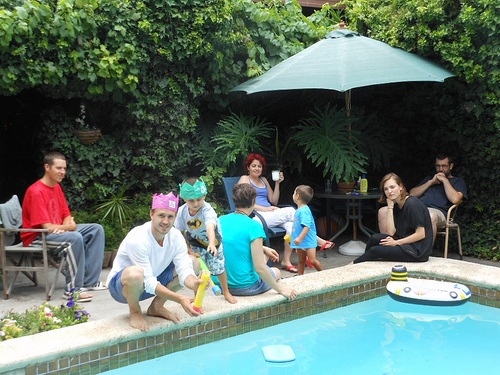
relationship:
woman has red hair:
[243, 153, 339, 274] [243, 148, 270, 170]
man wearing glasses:
[419, 150, 468, 237] [435, 161, 451, 168]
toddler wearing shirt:
[291, 181, 321, 286] [290, 205, 323, 254]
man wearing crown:
[100, 191, 203, 332] [149, 186, 180, 213]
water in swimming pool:
[380, 326, 471, 367] [7, 250, 499, 369]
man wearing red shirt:
[17, 148, 111, 305] [17, 174, 76, 251]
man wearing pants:
[17, 148, 111, 305] [27, 222, 115, 301]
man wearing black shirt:
[419, 150, 468, 237] [409, 170, 469, 214]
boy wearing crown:
[169, 176, 239, 307] [174, 181, 213, 202]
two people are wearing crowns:
[104, 176, 225, 329] [147, 176, 213, 211]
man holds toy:
[100, 191, 203, 332] [192, 269, 216, 311]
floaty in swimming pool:
[384, 263, 475, 310] [7, 250, 499, 369]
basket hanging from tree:
[72, 116, 112, 148] [6, 5, 156, 99]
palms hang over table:
[203, 115, 402, 177] [311, 180, 389, 245]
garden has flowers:
[0, 290, 91, 340] [66, 288, 82, 323]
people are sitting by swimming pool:
[8, 145, 469, 264] [7, 250, 499, 369]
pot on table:
[340, 174, 358, 191] [311, 180, 389, 245]